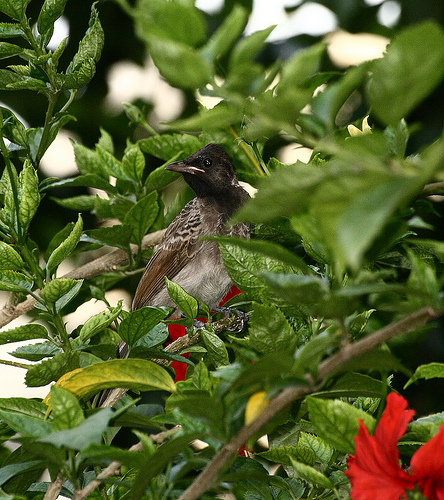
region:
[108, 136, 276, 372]
a bird on a plant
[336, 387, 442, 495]
a brilliant red flower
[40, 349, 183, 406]
a yellowing leaf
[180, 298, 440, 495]
a branch in a flower plant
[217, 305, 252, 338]
black claws on a bird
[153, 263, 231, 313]
a white belly on a bird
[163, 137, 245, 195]
a black head on a bird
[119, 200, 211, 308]
brown feathers on a bird's back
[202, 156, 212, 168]
a round black bird eye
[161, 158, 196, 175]
the beak of a bird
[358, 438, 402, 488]
the leaf is orange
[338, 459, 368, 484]
the leaf is orange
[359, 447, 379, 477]
the leaf is orange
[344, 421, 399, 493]
the leaf is orange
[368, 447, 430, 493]
the leaf is orange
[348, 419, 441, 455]
the leaf is orange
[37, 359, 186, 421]
The leaf is turning yellow.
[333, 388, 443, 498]
The flower is red.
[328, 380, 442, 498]
A flower in bloom.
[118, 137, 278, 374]
Bird sitting on a limb.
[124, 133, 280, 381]
Bird has many feathers.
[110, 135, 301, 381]
Bird with black eye.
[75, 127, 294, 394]
The bird is alert.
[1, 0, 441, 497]
The leaves are green.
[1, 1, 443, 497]
The leaves are healthy.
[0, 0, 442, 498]
The leaves are luxuriant.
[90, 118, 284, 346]
small black and grey bird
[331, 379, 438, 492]
bright red flower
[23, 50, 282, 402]
bird sitting in a tree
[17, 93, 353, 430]
deep green leaves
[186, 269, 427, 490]
smal branch with leaves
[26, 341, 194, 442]
yellowing leaf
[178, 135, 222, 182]
black beady eye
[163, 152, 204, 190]
grey beak with a streak of yellow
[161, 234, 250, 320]
soft white down on the birds belly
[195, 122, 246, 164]
tiny black mohawk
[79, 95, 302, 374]
a bird in the tree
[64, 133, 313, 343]
a bird in the bush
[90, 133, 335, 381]
a bird on the branch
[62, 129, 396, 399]
a bird with a black head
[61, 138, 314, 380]
bird with a brown wing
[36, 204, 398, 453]
green leaves on a branch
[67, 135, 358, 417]
a bird that is outside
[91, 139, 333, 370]
a bird with his head turned to the side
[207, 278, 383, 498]
a brown tree branch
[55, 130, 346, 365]
a bird awake during the day